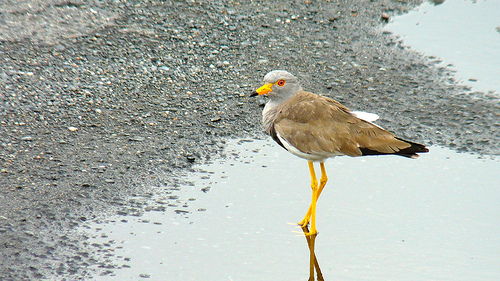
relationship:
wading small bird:
[291, 160, 331, 245] [236, 62, 427, 231]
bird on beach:
[236, 62, 427, 231] [9, 10, 486, 66]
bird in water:
[236, 62, 427, 231] [290, 231, 344, 254]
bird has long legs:
[236, 62, 427, 231] [302, 157, 325, 241]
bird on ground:
[236, 62, 427, 231] [139, 136, 252, 226]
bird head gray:
[236, 62, 427, 231] [274, 90, 285, 98]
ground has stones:
[139, 136, 252, 226] [184, 148, 214, 177]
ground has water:
[139, 136, 252, 226] [290, 231, 344, 254]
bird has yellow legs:
[236, 62, 427, 231] [302, 157, 325, 241]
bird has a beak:
[236, 62, 427, 231] [247, 80, 270, 100]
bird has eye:
[236, 62, 427, 231] [276, 77, 290, 88]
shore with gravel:
[419, 4, 480, 279] [363, 11, 416, 70]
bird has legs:
[236, 62, 427, 231] [308, 157, 319, 232]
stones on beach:
[184, 148, 214, 177] [9, 10, 486, 66]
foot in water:
[290, 214, 320, 240] [290, 231, 344, 254]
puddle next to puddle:
[400, 144, 491, 270] [431, 16, 484, 63]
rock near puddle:
[184, 151, 201, 168] [400, 144, 491, 270]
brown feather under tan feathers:
[343, 131, 376, 148] [315, 134, 329, 145]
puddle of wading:
[400, 144, 491, 270] [291, 160, 331, 245]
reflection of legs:
[299, 233, 325, 278] [302, 157, 325, 241]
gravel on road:
[363, 11, 416, 70] [71, 7, 383, 41]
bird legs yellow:
[236, 62, 427, 231] [311, 176, 320, 219]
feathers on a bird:
[305, 103, 361, 147] [236, 62, 427, 231]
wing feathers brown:
[281, 108, 368, 155] [337, 123, 356, 130]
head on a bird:
[250, 67, 305, 98] [236, 62, 427, 231]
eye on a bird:
[276, 77, 290, 88] [236, 62, 427, 231]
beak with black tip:
[247, 80, 270, 100] [246, 91, 258, 101]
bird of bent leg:
[236, 62, 427, 231] [307, 176, 337, 187]